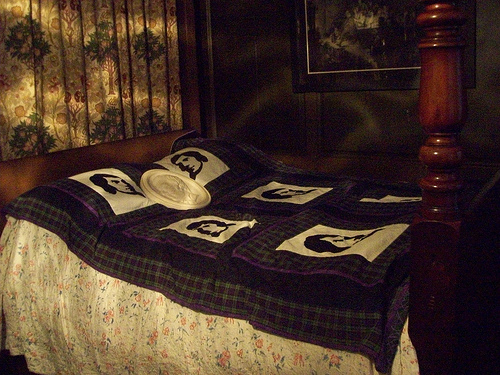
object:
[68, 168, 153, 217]
picture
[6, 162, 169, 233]
pillow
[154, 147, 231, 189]
picture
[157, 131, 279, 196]
pillow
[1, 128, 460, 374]
bed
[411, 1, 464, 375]
wood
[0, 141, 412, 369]
blanket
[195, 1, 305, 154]
wall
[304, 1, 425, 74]
picture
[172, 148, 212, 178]
man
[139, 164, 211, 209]
coin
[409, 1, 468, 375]
post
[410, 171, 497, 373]
headboard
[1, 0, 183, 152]
curtain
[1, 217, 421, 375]
blanket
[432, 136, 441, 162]
reflection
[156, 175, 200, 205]
head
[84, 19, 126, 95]
tree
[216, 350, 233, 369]
flower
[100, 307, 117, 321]
flower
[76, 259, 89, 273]
flower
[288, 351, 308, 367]
flower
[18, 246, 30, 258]
flower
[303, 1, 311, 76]
line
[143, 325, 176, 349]
flower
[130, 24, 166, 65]
tree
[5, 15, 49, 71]
tree